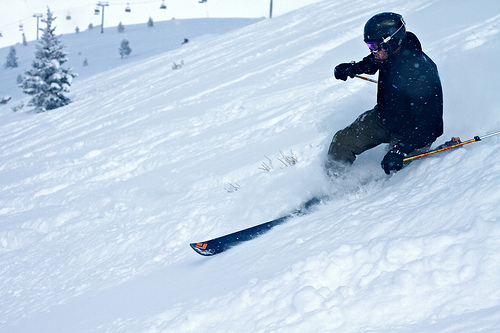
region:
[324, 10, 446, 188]
man dressed in black skiing down slope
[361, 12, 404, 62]
helmet the man is wearing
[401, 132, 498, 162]
ski pole in the man's left hand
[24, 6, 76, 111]
snow-covered pine tree at the edge of the trail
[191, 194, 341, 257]
front part of a black ski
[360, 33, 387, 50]
purple goggles the man is wearing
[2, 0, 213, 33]
ski lift going up another slope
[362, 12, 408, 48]
Black helmet on a man's head.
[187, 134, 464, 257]
A long black and orange ski.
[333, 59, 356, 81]
A right hand black glove.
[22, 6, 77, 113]
A large snowy pine tree.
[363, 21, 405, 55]
Purple black and white goggles.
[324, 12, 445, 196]
A man skiing with a black helmet on.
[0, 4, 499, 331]
A white snowy slope a man is skiing down.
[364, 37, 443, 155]
Black coat on a man.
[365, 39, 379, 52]
The purple tiny on goggles.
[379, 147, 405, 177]
A left black glove.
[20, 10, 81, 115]
a snow covered tree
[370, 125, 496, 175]
ski pole buried in snow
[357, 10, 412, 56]
ski helmet and goggles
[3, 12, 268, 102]
a snow covered slope in shadow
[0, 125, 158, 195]
powdered snow on a slope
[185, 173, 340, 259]
a buried snow ski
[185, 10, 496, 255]
a skier shredding the course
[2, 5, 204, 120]
trees dot the landscape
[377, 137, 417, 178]
a snow glove for skiing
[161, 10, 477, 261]
The person is going downhill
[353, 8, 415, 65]
The person has a helmet on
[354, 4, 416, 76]
The person has a black helmet on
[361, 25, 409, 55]
The person has goggles on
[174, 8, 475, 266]
The person is skiing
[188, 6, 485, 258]
The person is skiing downhill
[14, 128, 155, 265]
Large body of snow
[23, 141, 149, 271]
Large body of white snow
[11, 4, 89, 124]
Tree in the background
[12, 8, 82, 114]
The tree has snow on it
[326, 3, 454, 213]
man skiing down hill side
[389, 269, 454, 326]
white snow on hill side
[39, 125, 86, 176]
white snow on hill side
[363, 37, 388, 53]
purple goggles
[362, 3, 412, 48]
black helmet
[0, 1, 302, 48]
light in daytime sky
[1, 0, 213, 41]
ski lifts suspended from lines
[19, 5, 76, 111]
snow on tree limbs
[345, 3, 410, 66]
A Helmet for snowboarding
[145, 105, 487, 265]
The long black skii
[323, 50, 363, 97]
black glove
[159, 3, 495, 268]
person goes down the hill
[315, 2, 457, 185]
person wears black clothes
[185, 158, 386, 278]
the skies are long and black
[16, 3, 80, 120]
the tree is cover with snow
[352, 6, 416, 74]
the helmet is colro black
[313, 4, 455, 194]
the man is crouched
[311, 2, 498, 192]
person holds snow poles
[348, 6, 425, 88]
man wears sun glases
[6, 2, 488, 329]
field is covered with snow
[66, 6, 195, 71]
small trees on the snow